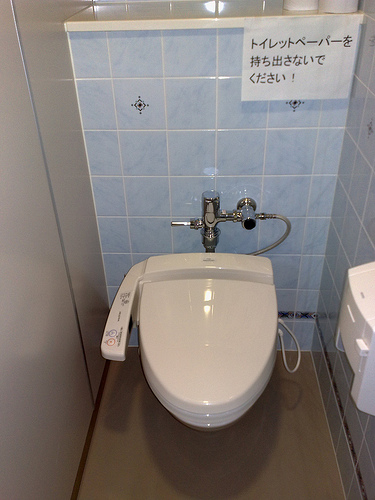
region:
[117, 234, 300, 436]
a white toilet.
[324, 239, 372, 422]
a white sink in a bathroom.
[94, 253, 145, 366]
a control panel on a toilet.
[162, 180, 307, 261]
a flushing mechanism on a wall.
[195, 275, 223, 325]
light reflecting on a toilet seat.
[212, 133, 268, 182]
a blue tile on a wall.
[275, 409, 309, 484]
a section of a bathroom floor.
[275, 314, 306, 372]
a hose on a toilet.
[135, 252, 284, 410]
a lid on a toilet seat.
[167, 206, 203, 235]
a flushing handle on a toilet.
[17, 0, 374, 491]
picture of a bathroom stall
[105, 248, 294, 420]
white toilet with the lid down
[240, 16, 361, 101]
white sign with black letters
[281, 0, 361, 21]
two rolls of white toilet paper on shelf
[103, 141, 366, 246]
square blue tile on walls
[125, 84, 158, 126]
small black design on scattered tiles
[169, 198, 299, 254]
silver plumbing behind toilet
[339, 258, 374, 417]
white toilet paper dispenser attached to wall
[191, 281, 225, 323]
light shining on toilet seat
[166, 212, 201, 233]
silver handle to flush toilet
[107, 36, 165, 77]
that is a tile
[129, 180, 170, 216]
that is a tile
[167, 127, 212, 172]
that is a tile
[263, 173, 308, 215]
that is a tile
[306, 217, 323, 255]
that is a tile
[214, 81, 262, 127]
that is a tile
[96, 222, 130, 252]
that is a tile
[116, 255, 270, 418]
this is a toilet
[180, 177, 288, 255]
that is a tap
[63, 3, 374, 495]
Blue tile wall with black accents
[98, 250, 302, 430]
White toliet with side bar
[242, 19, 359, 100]
White sign with black Chinese characters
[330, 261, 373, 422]
White toliet paper dispenser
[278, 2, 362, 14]
Two rolls of toliet paper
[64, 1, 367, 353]
Blue and white wall with white shelf on top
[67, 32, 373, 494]
Blue and white tile wall with black band at bottom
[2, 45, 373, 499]
Single empty toliet stall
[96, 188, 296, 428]
Toliet with silver hardware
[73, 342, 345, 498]
Tan floor with shadow of toliet bowl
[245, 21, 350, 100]
Written Japanese symbols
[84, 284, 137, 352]
instructions on side of toilet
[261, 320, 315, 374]
wire coming out of toilet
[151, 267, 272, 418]
clean white toilet seat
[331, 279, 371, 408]
white toilet paper dispenser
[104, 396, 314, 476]
spotless reflective brown floor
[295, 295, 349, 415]
multi-colored wall art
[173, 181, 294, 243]
shiny clean chrome backing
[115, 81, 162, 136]
flower like symbol on tile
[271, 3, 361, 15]
2 toilet paper rolls